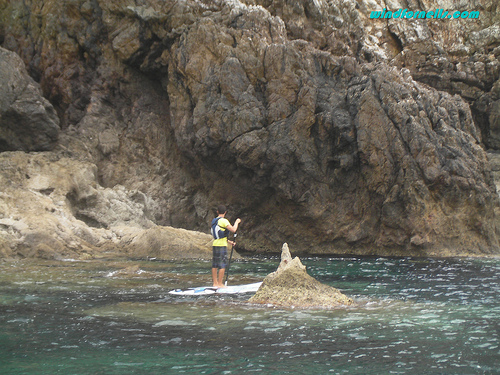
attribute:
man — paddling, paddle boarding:
[210, 203, 243, 287]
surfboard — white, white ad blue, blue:
[166, 281, 264, 298]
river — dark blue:
[4, 250, 499, 374]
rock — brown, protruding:
[250, 241, 354, 311]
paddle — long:
[225, 211, 247, 286]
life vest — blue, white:
[210, 216, 229, 239]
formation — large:
[1, 0, 498, 265]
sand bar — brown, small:
[88, 299, 463, 322]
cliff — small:
[111, 6, 176, 22]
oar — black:
[225, 216, 245, 289]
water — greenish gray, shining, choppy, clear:
[1, 251, 499, 374]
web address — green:
[364, 5, 484, 22]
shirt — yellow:
[212, 217, 232, 247]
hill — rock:
[2, 1, 499, 267]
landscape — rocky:
[0, 0, 500, 266]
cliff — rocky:
[228, 2, 473, 120]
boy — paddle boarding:
[210, 202, 244, 286]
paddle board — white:
[169, 281, 261, 297]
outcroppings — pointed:
[231, 1, 413, 86]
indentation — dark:
[370, 79, 430, 174]